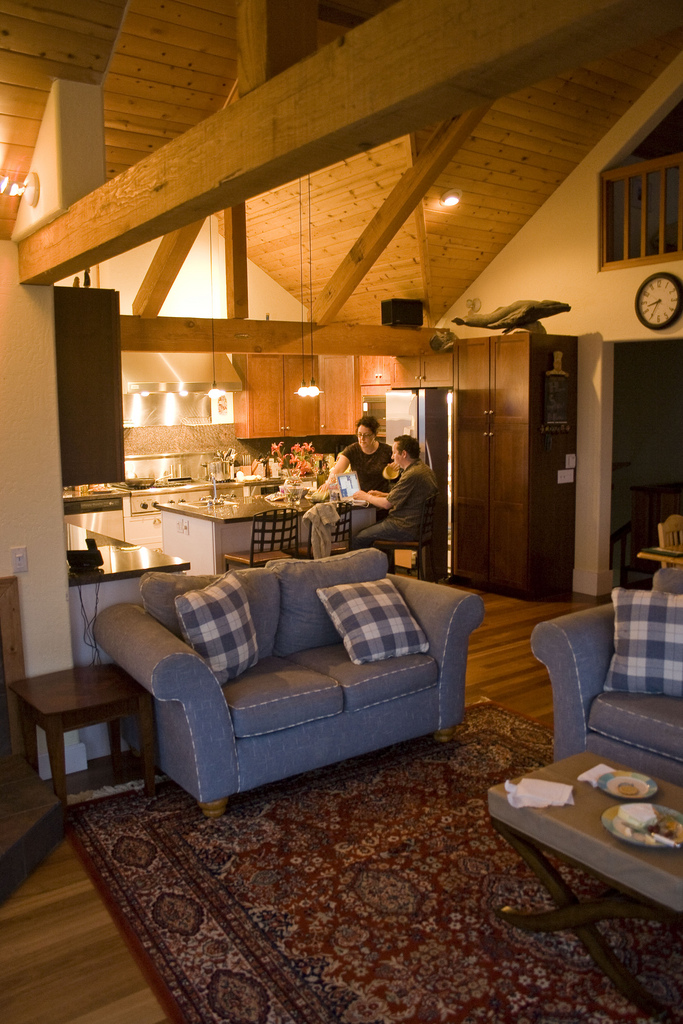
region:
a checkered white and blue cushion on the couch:
[312, 578, 429, 659]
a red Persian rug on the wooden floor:
[53, 694, 681, 1020]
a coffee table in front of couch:
[486, 751, 681, 1022]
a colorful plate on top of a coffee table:
[597, 768, 658, 801]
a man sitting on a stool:
[351, 434, 438, 577]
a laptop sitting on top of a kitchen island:
[335, 470, 367, 505]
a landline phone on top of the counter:
[64, 538, 103, 573]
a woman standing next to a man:
[314, 415, 391, 520]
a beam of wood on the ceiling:
[305, 97, 499, 327]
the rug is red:
[287, 862, 442, 974]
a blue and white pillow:
[611, 598, 673, 684]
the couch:
[112, 562, 474, 736]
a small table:
[22, 663, 103, 709]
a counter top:
[108, 552, 159, 573]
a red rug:
[256, 849, 434, 976]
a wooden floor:
[35, 936, 103, 991]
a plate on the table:
[602, 791, 682, 854]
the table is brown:
[28, 670, 124, 711]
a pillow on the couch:
[329, 584, 421, 667]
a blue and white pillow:
[350, 588, 407, 663]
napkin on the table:
[502, 764, 572, 808]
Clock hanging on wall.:
[633, 271, 681, 330]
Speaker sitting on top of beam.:
[379, 295, 426, 330]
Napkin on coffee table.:
[505, 777, 577, 813]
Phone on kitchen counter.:
[64, 536, 105, 576]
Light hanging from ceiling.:
[292, 180, 324, 403]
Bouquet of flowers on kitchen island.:
[270, 439, 315, 510]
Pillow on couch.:
[314, 575, 434, 665]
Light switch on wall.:
[7, 540, 32, 575]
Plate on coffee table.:
[592, 768, 659, 802]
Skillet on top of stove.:
[126, 472, 162, 489]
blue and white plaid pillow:
[313, 578, 423, 670]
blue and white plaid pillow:
[178, 581, 260, 677]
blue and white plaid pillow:
[608, 582, 682, 690]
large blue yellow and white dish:
[598, 801, 680, 850]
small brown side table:
[7, 661, 164, 806]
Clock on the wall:
[637, 270, 678, 337]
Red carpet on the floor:
[78, 715, 619, 998]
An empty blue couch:
[124, 559, 464, 759]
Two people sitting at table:
[317, 418, 435, 555]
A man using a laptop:
[330, 453, 435, 555]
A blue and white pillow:
[312, 575, 437, 703]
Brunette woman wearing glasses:
[344, 415, 398, 506]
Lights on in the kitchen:
[121, 358, 384, 554]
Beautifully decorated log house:
[6, 5, 680, 1000]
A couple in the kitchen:
[325, 407, 439, 556]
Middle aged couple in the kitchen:
[326, 401, 443, 550]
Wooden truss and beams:
[6, 5, 644, 343]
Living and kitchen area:
[5, 222, 678, 886]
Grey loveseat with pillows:
[90, 536, 501, 814]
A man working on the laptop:
[330, 433, 442, 575]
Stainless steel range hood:
[120, 352, 246, 401]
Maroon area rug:
[46, 694, 667, 1021]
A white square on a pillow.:
[237, 643, 253, 657]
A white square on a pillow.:
[198, 622, 219, 644]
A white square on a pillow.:
[224, 608, 245, 625]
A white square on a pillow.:
[239, 603, 250, 614]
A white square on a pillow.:
[209, 583, 229, 601]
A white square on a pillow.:
[224, 575, 244, 587]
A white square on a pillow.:
[188, 591, 215, 610]